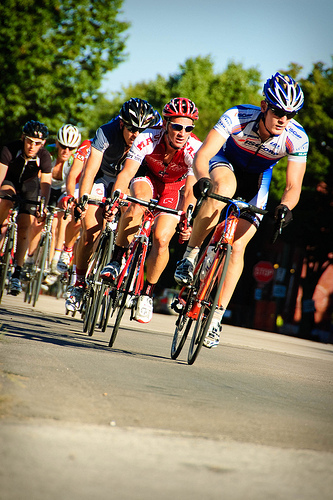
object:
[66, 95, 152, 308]
racer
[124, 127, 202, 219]
outfit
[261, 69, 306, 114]
helmet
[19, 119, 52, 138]
helmet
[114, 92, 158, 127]
helmet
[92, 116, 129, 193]
outfit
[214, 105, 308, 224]
blue/white outfit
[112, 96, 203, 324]
bike racer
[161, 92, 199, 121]
helmet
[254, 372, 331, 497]
road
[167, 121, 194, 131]
sunglasses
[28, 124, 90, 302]
bike racer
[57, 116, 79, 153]
safety helmet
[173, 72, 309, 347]
racer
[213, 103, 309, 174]
shirt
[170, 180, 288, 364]
bike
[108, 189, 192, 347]
bike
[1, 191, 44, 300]
bike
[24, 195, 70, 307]
bike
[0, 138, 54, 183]
shirt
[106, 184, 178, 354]
bike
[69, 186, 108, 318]
bike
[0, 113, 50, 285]
racer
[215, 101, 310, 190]
shirt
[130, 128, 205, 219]
shirt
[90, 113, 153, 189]
shirt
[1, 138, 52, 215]
shirt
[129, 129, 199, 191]
shirt